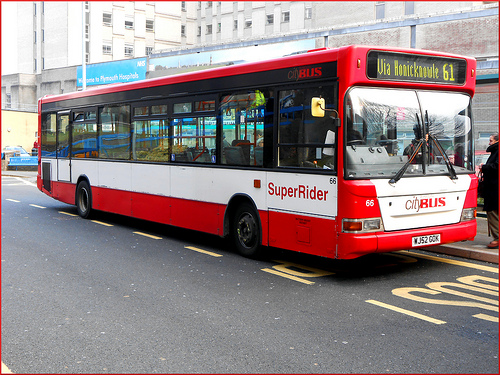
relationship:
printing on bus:
[269, 182, 328, 203] [37, 45, 477, 260]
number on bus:
[442, 63, 456, 82] [37, 45, 477, 260]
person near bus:
[477, 133, 500, 249] [37, 45, 477, 260]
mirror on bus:
[311, 97, 341, 128] [37, 45, 477, 260]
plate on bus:
[411, 232, 441, 247] [37, 45, 477, 260]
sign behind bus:
[77, 59, 149, 89] [37, 45, 477, 260]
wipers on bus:
[389, 111, 458, 184] [37, 45, 477, 260]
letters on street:
[271, 252, 499, 337] [0, 171, 499, 373]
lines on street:
[0, 175, 498, 327] [0, 171, 499, 373]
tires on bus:
[75, 179, 265, 260] [37, 45, 477, 260]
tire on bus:
[74, 181, 93, 218] [37, 45, 477, 260]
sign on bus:
[365, 48, 467, 86] [37, 45, 477, 260]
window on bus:
[277, 85, 339, 175] [37, 45, 477, 260]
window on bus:
[99, 105, 133, 162] [37, 45, 477, 260]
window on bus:
[69, 109, 99, 159] [37, 45, 477, 260]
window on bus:
[132, 104, 170, 163] [37, 45, 477, 260]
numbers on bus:
[365, 200, 375, 207] [37, 45, 477, 260]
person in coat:
[477, 133, 500, 249] [481, 142, 500, 211]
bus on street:
[37, 45, 477, 260] [0, 171, 499, 373]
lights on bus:
[342, 216, 383, 236] [37, 45, 477, 260]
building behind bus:
[16, 1, 500, 74] [37, 45, 477, 260]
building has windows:
[16, 1, 500, 74] [32, 2, 290, 74]